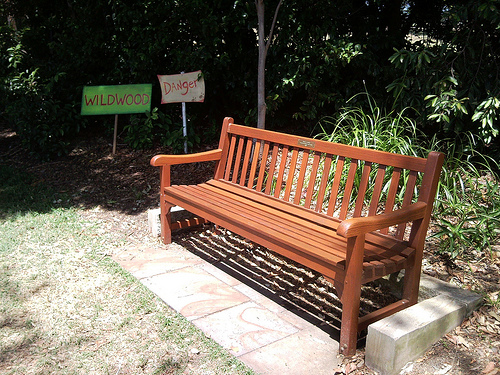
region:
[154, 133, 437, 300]
long brown wooden bench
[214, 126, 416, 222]
wooden back of bench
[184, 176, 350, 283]
brown wooden bottom of bench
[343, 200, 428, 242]
brown arm rest of bench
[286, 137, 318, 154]
small log on back of bench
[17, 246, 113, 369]
dead grass in front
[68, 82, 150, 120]
green sign on stick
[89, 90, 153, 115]
red writing on the sign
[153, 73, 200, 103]
white sign on pole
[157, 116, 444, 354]
a brown park bench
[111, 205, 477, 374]
a concrete slab under the bench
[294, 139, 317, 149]
brass plaque on center back of bench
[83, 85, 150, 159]
a green sign with red writing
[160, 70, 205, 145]
a white sign with red writing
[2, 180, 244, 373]
grass in front of the bench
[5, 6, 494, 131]
green trees behind the bench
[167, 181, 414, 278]
the seat on the bench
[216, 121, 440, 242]
the bench's back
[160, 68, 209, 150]
a danger sign on a white stake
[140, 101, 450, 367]
An empty bench near a wooded area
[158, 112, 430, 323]
Bench is brown color.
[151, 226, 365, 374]
Tiles are under the bench.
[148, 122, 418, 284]
Bench is made of wood.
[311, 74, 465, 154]
Plants are green color.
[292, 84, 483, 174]
Plants are behind the bench.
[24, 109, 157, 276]
Shadow falls on ground.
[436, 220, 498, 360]
Dried leaves on ground.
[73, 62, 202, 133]
Two boards are on side of bench.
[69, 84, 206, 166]
Boards are attached to the pole.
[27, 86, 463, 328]
Day time picture.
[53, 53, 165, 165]
a green sign with red words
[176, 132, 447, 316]
a wooden park bench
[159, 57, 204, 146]
a sign that reads danger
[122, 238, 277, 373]
blocks on the ground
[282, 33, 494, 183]
dense green foliage behind the bench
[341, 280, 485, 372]
a block defining the space for the bench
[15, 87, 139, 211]
a dark shadow hangs over the signs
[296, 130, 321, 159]
a plaque on the back of the bench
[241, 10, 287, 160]
a single tree of grey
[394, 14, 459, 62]
looks to be bright sun